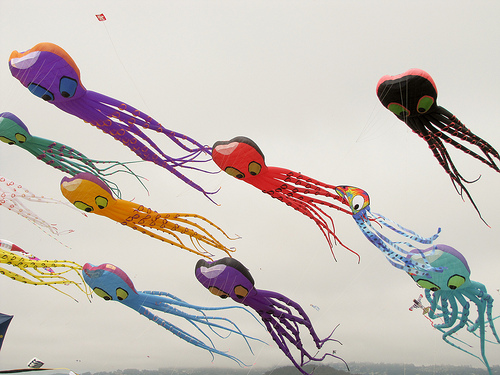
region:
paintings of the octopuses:
[182, 193, 459, 358]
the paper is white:
[335, 297, 393, 344]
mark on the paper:
[92, 13, 115, 35]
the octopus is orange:
[115, 203, 127, 219]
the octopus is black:
[395, 79, 436, 99]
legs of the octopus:
[15, 255, 65, 295]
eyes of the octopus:
[31, 75, 83, 104]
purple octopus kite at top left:
[12, 44, 212, 190]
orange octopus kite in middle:
[205, 123, 355, 250]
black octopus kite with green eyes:
[365, 63, 492, 203]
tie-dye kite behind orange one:
[332, 172, 457, 279]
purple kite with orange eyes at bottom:
[190, 238, 347, 360]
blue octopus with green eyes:
[102, 273, 213, 342]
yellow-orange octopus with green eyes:
[64, 167, 245, 268]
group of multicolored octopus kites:
[7, 37, 492, 365]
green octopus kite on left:
[7, 108, 125, 193]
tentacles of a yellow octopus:
[4, 260, 120, 306]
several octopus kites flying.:
[0, 10, 498, 370]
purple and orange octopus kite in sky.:
[7, 41, 209, 191]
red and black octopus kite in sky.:
[205, 135, 352, 235]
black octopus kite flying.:
[370, 66, 486, 181]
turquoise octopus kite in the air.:
[401, 246, 496, 361]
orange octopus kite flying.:
[57, 170, 232, 255]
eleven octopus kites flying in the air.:
[0, 45, 496, 350]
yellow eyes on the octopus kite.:
[72, 195, 107, 210]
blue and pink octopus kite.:
[75, 256, 206, 346]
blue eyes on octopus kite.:
[22, 76, 79, 104]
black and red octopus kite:
[372, 67, 498, 230]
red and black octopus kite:
[204, 133, 377, 270]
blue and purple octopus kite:
[395, 243, 498, 373]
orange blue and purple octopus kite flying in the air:
[5, 38, 235, 211]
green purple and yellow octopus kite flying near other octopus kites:
[0, 110, 150, 217]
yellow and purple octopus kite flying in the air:
[58, 169, 245, 270]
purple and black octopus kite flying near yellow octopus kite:
[193, 255, 351, 373]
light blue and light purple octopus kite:
[81, 260, 273, 371]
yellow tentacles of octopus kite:
[0, 246, 95, 313]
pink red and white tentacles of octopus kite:
[0, 172, 96, 252]